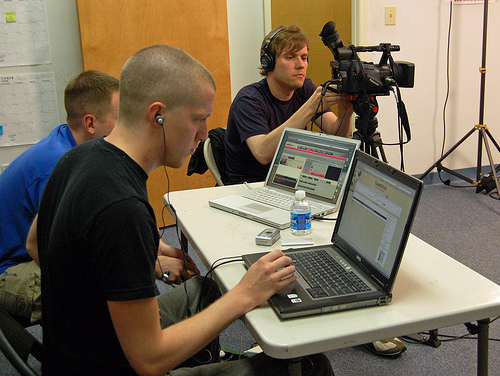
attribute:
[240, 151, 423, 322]
laptop — black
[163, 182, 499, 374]
table — white, small, rectangle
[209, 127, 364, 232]
laptop — white, silver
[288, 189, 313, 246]
bottle — plastic, small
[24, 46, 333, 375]
guy — young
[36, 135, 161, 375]
tshirt — black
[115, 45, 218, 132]
hair — short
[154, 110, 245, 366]
earphones — large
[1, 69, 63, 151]
calendar — hanging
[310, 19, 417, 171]
recording equipment — black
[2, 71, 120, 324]
man — young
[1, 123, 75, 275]
tshirt — blue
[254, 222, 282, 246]
cell phone — gray, silver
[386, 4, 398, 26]
light switch — rectangle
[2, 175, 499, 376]
floor — gray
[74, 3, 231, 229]
door — brown